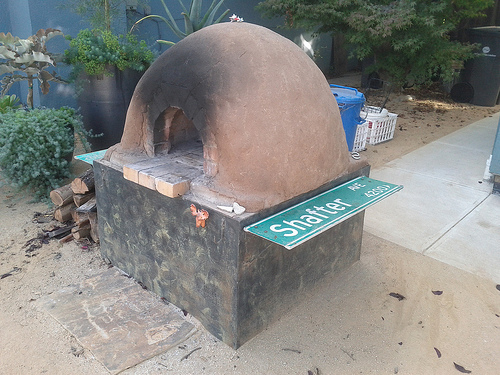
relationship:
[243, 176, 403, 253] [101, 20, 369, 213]
sign on side of oven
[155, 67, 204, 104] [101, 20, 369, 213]
residue on oven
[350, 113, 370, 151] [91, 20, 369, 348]
crate behind oven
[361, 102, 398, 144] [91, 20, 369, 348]
crate behind oven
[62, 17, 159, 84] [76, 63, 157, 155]
plant are in container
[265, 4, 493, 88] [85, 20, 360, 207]
tree behind oven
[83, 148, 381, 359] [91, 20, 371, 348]
stand for oven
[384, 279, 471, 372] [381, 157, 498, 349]
leaves on ground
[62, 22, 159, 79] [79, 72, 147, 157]
plant in pot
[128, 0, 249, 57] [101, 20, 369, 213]
plant behind oven